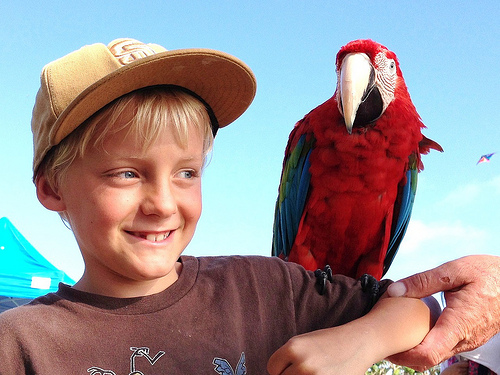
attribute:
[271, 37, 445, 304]
parrot — colorful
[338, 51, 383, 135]
beak — large, white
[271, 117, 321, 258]
wing — green, blue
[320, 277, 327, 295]
talon — sharp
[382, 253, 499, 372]
hand — adult hand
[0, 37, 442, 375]
kid — smiling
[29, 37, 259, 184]
baseball cap — light colored, brown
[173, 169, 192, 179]
eye — blue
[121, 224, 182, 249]
mouth — smiling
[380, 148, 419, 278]
left wing — blue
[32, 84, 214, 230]
hair — blond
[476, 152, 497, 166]
kite — colorful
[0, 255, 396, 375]
shirt — brown